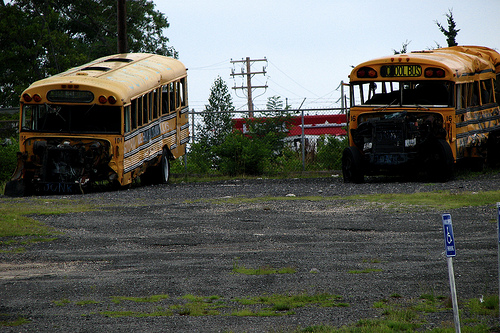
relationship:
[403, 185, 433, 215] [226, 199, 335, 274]
grass on road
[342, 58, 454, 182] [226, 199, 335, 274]
bus on road